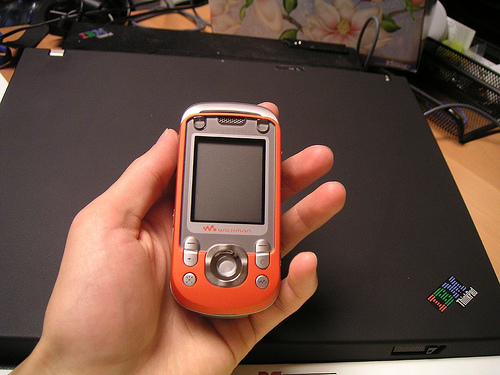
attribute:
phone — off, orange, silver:
[170, 99, 279, 317]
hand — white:
[40, 100, 350, 367]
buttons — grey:
[182, 235, 273, 290]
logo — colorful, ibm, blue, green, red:
[423, 274, 483, 320]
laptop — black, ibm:
[357, 85, 500, 353]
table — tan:
[468, 138, 500, 215]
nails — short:
[150, 126, 174, 149]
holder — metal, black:
[422, 39, 499, 137]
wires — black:
[131, 1, 207, 31]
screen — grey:
[193, 134, 273, 226]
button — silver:
[207, 245, 248, 287]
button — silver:
[183, 272, 197, 287]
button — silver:
[255, 274, 270, 291]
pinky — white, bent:
[280, 250, 314, 327]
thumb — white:
[88, 128, 178, 235]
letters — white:
[453, 287, 484, 312]